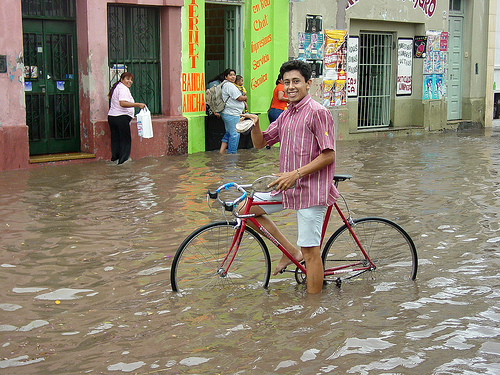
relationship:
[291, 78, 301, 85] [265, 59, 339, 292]
eye of man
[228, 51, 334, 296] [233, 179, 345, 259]
man wearing short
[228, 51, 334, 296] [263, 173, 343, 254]
man wearing short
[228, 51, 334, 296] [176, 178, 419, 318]
man on bike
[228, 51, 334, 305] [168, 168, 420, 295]
man on bicycle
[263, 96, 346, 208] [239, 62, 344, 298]
shirt on man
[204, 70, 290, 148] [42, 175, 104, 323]
people standing street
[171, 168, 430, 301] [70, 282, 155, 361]
bicycle flooded street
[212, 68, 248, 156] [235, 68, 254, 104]
people holding baby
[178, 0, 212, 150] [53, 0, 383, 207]
sign outside of building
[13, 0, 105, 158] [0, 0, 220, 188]
door on side of building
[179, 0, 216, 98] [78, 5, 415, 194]
writing on building